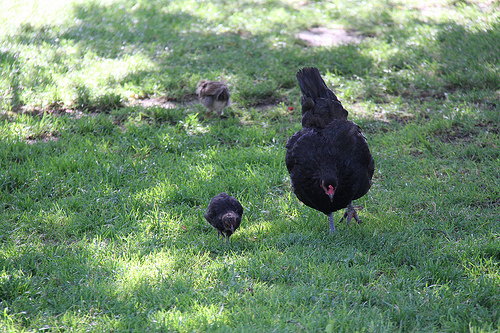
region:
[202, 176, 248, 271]
a black baby chicken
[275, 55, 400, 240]
a black chicken walking in the grass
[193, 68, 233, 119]
a soft fluffy brown chicken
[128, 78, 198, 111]
a dirt patch in the grass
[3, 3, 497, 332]
a grassy yard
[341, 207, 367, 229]
a lifted foot of a chicken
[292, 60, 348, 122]
black tail feathers of a chicken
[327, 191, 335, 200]
the beak of a chicken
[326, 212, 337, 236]
the leg of a chicken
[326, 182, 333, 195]
a red chicken comb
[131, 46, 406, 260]
three black chickens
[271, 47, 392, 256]
black chicken with red on head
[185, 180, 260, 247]
young black chicken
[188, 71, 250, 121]
baby chicken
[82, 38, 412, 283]
family of chickens walking in the grass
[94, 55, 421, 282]
baby chick following two other chickens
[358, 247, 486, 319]
patch of green grass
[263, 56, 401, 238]
chicken walking across the grass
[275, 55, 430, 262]
bird with tail towards the air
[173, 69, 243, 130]
gray round baby bird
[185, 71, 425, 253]
two birds on the grass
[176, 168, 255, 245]
baby bird next to big bird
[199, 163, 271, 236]
black bird on ground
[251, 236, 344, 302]
shadow on the ground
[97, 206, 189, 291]
light and dark spots on ground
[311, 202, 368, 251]
feet of the bird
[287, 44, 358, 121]
tail feather of the bird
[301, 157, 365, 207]
head of the bird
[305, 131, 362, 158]
black feathers on the bird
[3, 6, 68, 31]
light hitting the grass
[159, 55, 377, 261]
Three chickens in the grass.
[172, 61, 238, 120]
The baby chick is behind the mother.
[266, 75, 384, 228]
The chicken is black.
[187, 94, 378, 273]
A little chick and big chicken next to each other.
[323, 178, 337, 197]
The chicken has a red beak.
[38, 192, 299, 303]
The grass is green.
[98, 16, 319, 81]
The sun is shining in the grass.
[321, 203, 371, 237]
The chicken has skinny legs.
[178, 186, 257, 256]
The little chicken is eating grass.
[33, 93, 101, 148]
Patches of dirt in the grass.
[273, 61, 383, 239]
A large black chicken walking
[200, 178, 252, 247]
A small black chick walking with the chicken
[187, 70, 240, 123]
A brown and white chick in the background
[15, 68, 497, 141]
A line of dirt patches in the grass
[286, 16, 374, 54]
A round dirt patch in the grass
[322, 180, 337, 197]
A red crest on the black chicken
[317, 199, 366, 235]
The chicken's gray talons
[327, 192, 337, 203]
The chicken's shiny, dark gray beak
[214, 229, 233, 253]
The chick's tiny gray talons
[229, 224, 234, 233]
The chick's tiny, shiny gray beak